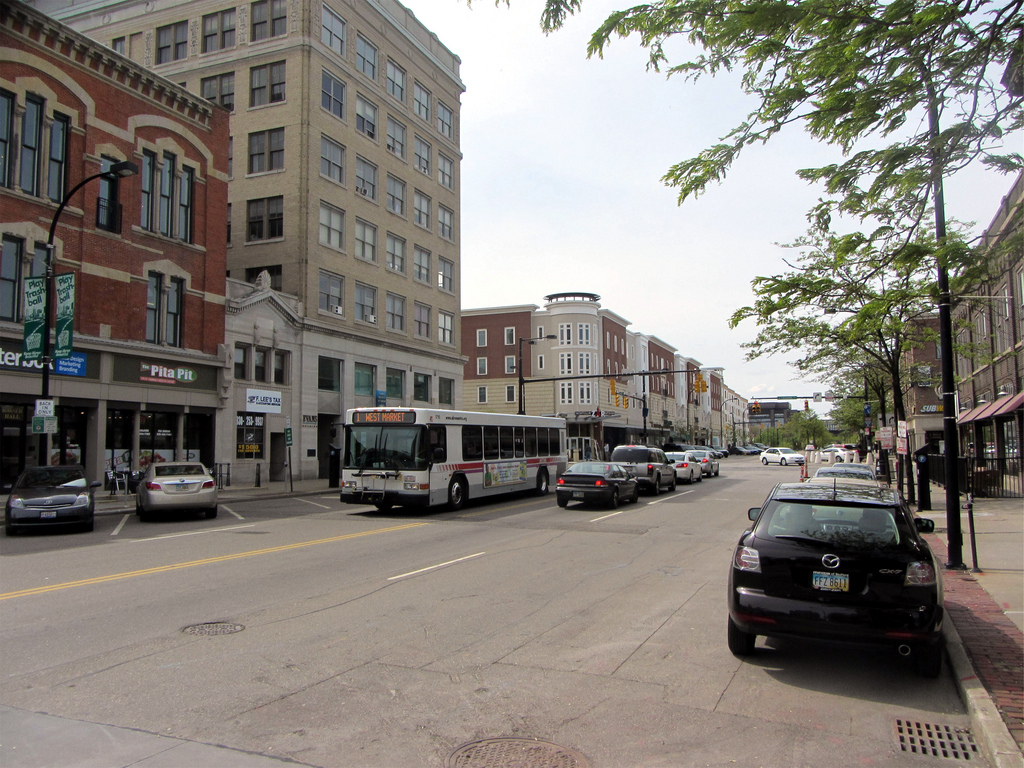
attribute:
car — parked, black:
[728, 481, 948, 694]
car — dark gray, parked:
[0, 466, 94, 527]